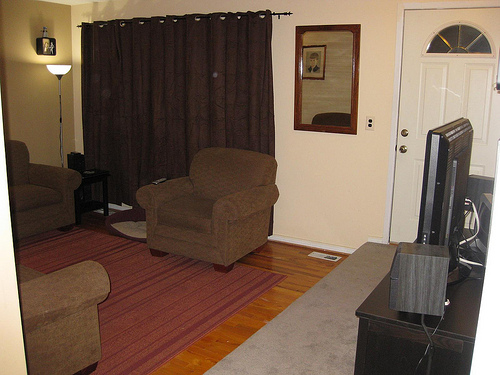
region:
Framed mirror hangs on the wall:
[291, 23, 363, 133]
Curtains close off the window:
[72, 9, 279, 236]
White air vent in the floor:
[306, 246, 342, 263]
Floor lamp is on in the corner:
[44, 63, 71, 167]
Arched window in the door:
[418, 18, 498, 60]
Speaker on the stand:
[386, 241, 451, 317]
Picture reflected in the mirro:
[301, 43, 327, 80]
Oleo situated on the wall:
[36, 28, 57, 55]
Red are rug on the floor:
[18, 220, 288, 373]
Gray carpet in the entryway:
[192, 248, 414, 374]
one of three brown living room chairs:
[16, 256, 112, 373]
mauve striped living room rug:
[15, 225, 287, 373]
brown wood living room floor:
[149, 237, 349, 373]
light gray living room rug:
[205, 242, 402, 373]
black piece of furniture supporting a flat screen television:
[354, 228, 496, 373]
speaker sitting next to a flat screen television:
[385, 240, 457, 319]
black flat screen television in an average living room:
[415, 115, 471, 282]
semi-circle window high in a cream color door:
[421, 19, 496, 55]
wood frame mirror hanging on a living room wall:
[293, 23, 360, 134]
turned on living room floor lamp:
[44, 63, 71, 165]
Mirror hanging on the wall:
[294, 24, 358, 135]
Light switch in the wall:
[365, 114, 375, 129]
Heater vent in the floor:
[308, 249, 341, 263]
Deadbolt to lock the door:
[400, 128, 407, 137]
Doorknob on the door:
[400, 145, 407, 154]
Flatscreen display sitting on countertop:
[413, 118, 473, 288]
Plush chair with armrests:
[134, 145, 280, 273]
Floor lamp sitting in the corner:
[44, 63, 71, 165]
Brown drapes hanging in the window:
[80, 10, 275, 235]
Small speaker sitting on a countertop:
[390, 241, 449, 318]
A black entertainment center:
[353, 221, 476, 373]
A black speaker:
[388, 240, 448, 323]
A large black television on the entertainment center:
[415, 116, 471, 283]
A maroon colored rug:
[12, 225, 287, 371]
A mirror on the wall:
[293, 25, 356, 132]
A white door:
[390, 5, 496, 245]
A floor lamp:
[45, 60, 71, 165]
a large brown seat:
[135, 148, 277, 270]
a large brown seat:
[10, 260, 110, 373]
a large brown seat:
[3, 140, 81, 240]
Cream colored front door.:
[385, 5, 499, 258]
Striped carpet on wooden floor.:
[17, 213, 359, 373]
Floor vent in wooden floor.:
[306, 245, 350, 265]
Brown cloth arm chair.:
[136, 143, 288, 273]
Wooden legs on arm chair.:
[136, 148, 276, 275]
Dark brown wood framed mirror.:
[288, 20, 363, 140]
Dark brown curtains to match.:
[76, 9, 277, 247]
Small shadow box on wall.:
[35, 19, 59, 59]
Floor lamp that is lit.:
[45, 60, 78, 172]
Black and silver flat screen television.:
[416, 117, 474, 287]